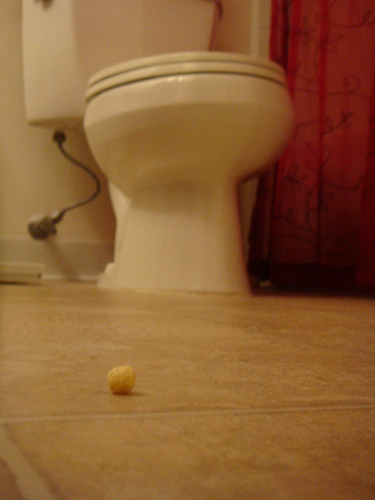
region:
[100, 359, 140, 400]
A singular cear corn puff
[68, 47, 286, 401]
A piece of cereal resting on the floor in front of a toilet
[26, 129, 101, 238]
Water intake hose for a toilet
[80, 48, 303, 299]
Bottom portion of a white toilet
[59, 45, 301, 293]
Bottom half of a white toilet as seen from the floor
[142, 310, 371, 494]
An area of tan linoleum flooring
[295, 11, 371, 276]
Part of a red embroidered shower curtain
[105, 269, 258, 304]
Caulking aroung the base of a toilet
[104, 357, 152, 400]
A piece of cereal and its shadow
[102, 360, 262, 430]
A piece of corn cereal on the floor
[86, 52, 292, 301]
Cream colored toilet seat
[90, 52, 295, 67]
Cream colored toilet lead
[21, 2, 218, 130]
Cream colored toilet tank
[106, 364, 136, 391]
Yellow ball on floor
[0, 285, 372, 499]
Brown colored toilet floor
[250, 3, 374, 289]
Red colored curtain in toilet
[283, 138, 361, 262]
Black flowers on red curtain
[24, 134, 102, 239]
Grey colored small pipe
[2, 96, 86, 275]
Beige wall in toilet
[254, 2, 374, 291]
Curtain beside a toilet seat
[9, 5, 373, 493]
a toilet is in a bathroom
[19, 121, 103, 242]
the toilet's plumbing is on the wall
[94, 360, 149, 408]
a ball is on the bathroom floor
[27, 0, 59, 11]
the toilet's handle is chrome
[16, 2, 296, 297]
the toilet is white porcelain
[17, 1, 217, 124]
the water closet of the toilet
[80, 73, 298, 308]
the bowl of the toilet is in the bathroom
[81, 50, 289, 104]
the lid and seat are closed on the toilet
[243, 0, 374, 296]
the shower curtain is red in the bathroom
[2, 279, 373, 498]
the floor of the bathroom is tiled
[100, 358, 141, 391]
ball on the floor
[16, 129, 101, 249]
water pipe connected to the toilet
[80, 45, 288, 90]
toilet lid down on the toilet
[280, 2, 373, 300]
red curtain next to the toilet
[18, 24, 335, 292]
Toilet in the bathroom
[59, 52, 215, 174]
Toilet in the bathroom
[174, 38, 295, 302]
Toilet in the bathroom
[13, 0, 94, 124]
Toilet in the bathroom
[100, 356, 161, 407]
food on the floor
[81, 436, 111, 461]
part of the floor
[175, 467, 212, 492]
part of the floor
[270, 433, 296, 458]
part of the floor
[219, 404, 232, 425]
part of the floor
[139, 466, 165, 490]
part of the floor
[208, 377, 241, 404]
part of the floor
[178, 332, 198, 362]
part of the floor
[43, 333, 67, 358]
part of the floor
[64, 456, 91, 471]
part of the floor